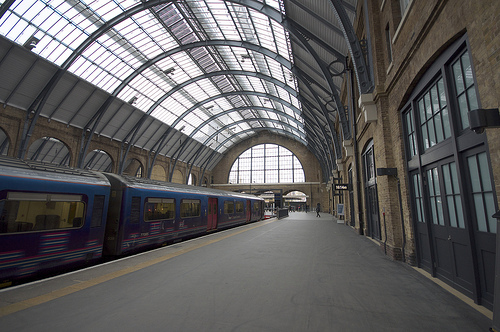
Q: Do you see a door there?
A: Yes, there are doors.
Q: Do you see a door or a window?
A: Yes, there are doors.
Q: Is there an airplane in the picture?
A: No, there are no airplanes.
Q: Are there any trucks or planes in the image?
A: No, there are no planes or trucks.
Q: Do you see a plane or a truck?
A: No, there are no airplanes or trucks.